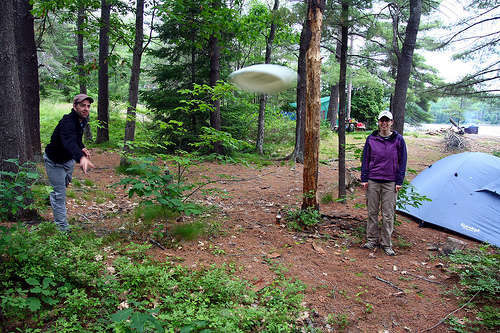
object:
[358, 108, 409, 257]
woman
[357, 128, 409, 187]
jacket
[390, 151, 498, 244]
tent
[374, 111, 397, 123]
hat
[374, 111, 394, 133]
head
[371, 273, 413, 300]
twigs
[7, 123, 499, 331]
ground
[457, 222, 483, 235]
logo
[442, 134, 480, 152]
branches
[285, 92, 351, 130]
shack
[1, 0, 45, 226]
tree trunk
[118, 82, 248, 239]
tree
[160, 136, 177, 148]
leaves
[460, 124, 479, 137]
grill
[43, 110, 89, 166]
coat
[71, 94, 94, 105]
cap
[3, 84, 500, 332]
campground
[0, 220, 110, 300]
plants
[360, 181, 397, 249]
pants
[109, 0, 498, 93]
sky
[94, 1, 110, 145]
tree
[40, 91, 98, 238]
person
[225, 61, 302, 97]
frisbee